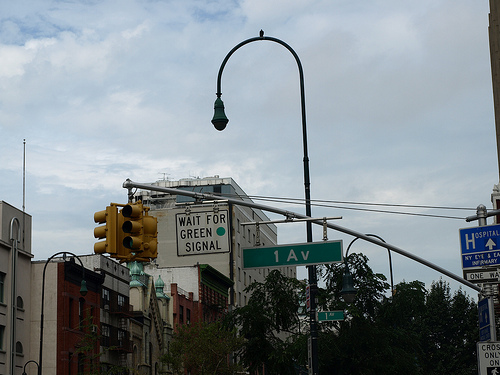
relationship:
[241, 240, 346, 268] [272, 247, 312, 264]
sign has 1 av.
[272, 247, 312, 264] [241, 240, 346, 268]
number on sign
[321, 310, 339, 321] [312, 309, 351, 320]
number on sign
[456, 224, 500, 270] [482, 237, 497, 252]
sign pointing arrow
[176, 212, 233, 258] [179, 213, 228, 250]
sign has lettering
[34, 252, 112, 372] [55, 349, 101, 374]
building has a story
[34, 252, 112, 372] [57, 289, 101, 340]
building has a story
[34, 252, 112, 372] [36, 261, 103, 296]
building has a story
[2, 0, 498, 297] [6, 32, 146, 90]
sky has cloud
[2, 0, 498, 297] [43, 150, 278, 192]
sky has cloud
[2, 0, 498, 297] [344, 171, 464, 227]
sky has cloud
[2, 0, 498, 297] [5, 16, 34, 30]
sky has spot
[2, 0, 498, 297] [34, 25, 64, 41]
sky has spot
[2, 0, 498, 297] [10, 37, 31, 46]
sky has spot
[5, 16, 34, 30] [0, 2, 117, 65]
spot in left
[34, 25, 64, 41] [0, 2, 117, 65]
spot in left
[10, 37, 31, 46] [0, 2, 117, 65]
spot in left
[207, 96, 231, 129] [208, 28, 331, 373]
light on pole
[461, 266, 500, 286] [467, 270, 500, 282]
sign points to right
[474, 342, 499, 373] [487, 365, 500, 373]
sign for pedestrian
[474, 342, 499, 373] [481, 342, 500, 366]
sign with instructions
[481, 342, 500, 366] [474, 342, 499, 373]
instructions about sign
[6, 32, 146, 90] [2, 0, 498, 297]
cloud in sky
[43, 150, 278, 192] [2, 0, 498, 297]
cloud in sky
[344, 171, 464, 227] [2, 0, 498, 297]
cloud in sky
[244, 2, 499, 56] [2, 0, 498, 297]
cloud in sky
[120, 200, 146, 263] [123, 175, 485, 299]
light hanging from pole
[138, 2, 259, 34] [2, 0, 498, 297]
cloud in sky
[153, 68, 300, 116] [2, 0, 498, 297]
cloud in sky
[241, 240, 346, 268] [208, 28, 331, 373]
sign on pole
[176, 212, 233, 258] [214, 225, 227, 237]
sign has dot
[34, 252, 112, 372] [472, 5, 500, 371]
building across street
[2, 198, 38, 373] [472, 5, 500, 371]
building across street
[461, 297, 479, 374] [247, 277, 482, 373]
tree in distance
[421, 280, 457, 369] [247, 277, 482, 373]
tree in distance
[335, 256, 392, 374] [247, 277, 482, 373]
tree in distance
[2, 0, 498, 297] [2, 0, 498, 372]
sky over town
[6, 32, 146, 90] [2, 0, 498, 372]
cloud over town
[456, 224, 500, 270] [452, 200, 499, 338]
sign on post